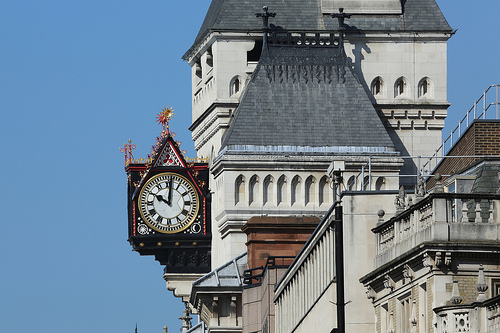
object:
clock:
[136, 171, 198, 235]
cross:
[255, 1, 277, 41]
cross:
[328, 6, 352, 31]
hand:
[146, 190, 171, 206]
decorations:
[162, 105, 174, 133]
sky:
[16, 69, 87, 142]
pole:
[329, 199, 349, 326]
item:
[156, 112, 170, 127]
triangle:
[148, 133, 188, 167]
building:
[117, 9, 500, 333]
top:
[148, 103, 187, 141]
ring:
[137, 171, 202, 231]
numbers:
[176, 216, 182, 222]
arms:
[165, 180, 176, 204]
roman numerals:
[156, 183, 163, 190]